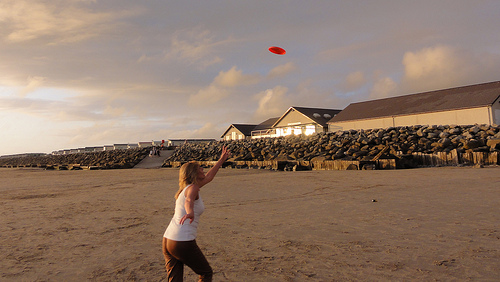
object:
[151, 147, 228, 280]
lady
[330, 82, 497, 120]
roof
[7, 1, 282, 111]
sky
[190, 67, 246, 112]
cloud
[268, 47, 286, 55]
frisbee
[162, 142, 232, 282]
girl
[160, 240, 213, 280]
pants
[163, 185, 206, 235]
top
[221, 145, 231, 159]
left hand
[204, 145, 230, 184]
arm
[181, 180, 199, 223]
arm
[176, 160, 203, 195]
hair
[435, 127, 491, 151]
rocks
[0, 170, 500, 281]
beach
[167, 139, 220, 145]
houses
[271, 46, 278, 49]
logo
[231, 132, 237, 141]
doors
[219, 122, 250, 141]
house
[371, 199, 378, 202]
rock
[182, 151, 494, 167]
barriers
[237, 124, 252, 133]
roof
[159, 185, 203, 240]
shirt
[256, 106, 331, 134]
house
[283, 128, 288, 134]
windows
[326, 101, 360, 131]
houses